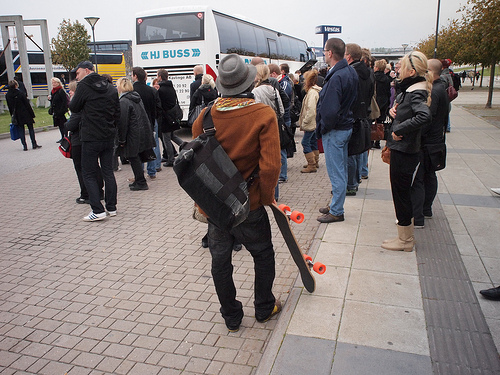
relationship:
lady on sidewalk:
[380, 50, 436, 252] [256, 103, 499, 373]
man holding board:
[192, 55, 282, 331] [269, 201, 327, 293]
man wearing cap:
[192, 55, 282, 331] [215, 52, 258, 95]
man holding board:
[192, 55, 282, 331] [267, 200, 333, 296]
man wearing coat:
[192, 55, 282, 331] [189, 96, 283, 224]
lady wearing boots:
[377, 46, 428, 253] [374, 221, 419, 253]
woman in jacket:
[121, 71, 162, 193] [113, 92, 153, 158]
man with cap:
[410, 58, 450, 228] [215, 52, 258, 95]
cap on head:
[215, 52, 258, 95] [321, 38, 346, 67]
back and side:
[131, 4, 219, 115] [210, 10, 314, 85]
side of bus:
[210, 10, 314, 85] [131, 2, 316, 124]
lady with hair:
[380, 50, 436, 252] [402, 50, 429, 77]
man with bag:
[192, 55, 282, 331] [174, 136, 249, 234]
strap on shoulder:
[203, 100, 218, 135] [194, 97, 223, 137]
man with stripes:
[68, 62, 120, 223] [86, 212, 97, 221]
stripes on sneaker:
[86, 212, 97, 221] [83, 210, 108, 222]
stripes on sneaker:
[86, 212, 97, 221] [108, 210, 118, 217]